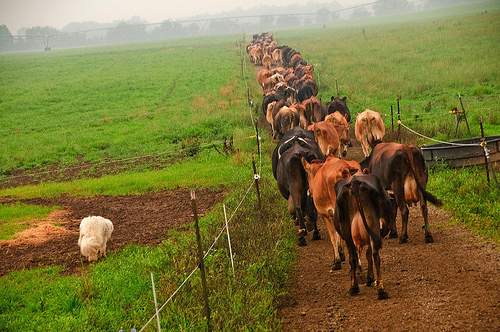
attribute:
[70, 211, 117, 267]
dog — furry, white, not sheep, snuffling, concentrating, ignoring cattle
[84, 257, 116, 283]
grass — thick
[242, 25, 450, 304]
herd — large, of cattle, crowded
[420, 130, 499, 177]
tub — large, metal, maybe trough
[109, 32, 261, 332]
fence — metal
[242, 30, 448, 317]
cattle — not sheep, very organized, walking steadily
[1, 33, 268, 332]
field — grass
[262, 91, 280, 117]
cow — black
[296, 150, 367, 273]
cow — brown, red brown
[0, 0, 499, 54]
fog — on the horizon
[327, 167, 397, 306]
cow — dark brown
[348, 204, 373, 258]
udder — large, full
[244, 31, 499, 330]
trail — dirt, brown, cow path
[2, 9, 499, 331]
field — pasture, green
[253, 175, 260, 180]
sheep — but an illusion, maybe delusion too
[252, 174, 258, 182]
sheep — a lie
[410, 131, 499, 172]
trough — water trough, round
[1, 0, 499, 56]
trees — plentiful, on the horizon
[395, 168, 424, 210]
udder — full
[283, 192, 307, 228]
udder — full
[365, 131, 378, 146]
udder — full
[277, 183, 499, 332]
cow path — very slightly muddy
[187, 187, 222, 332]
post — fencepost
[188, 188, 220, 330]
fence post — wooden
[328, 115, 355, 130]
tail — swishing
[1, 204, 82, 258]
sand — maybe potting soil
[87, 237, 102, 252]
ear — floppy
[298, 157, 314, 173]
ear — red brown